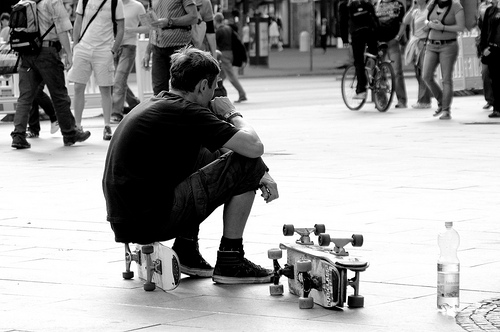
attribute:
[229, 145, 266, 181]
knee — leg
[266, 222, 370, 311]
skateboards — stacked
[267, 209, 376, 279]
skateboard — upside down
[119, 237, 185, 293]
skateboard — flipped